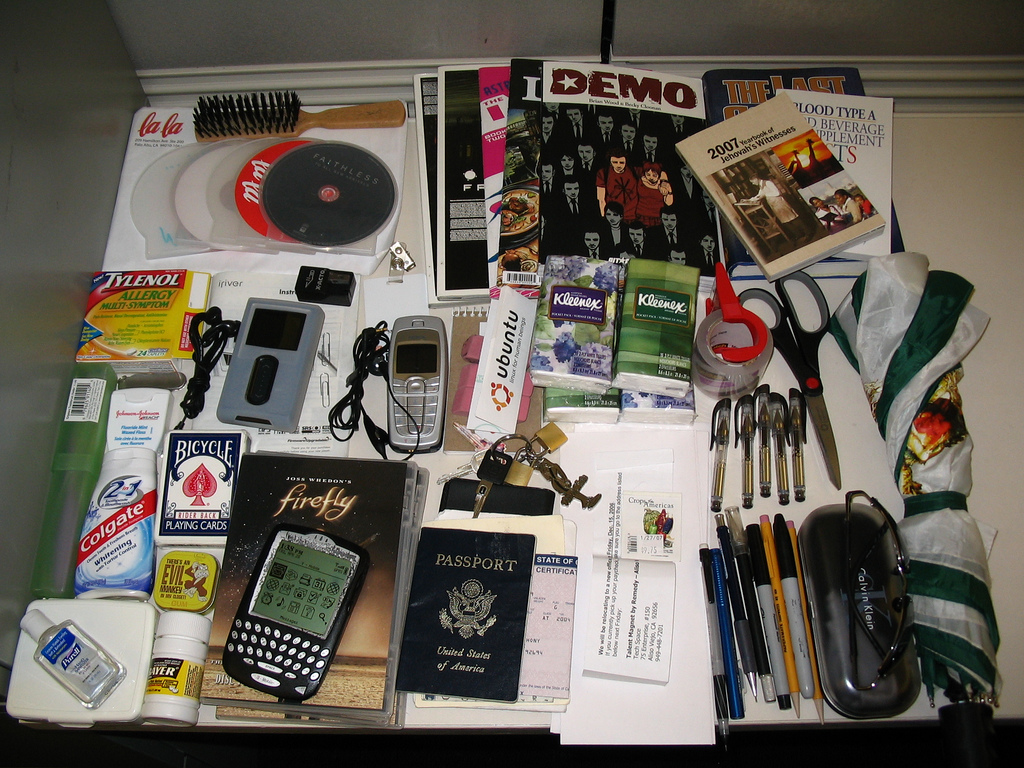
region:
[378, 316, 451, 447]
cell phone on the table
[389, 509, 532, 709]
passport on the table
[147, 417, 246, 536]
deck of card on the table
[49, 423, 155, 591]
toothpaste on the table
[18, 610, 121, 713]
hand sanitize on the table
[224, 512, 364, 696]
blackberry on the table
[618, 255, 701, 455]
kleenex on the table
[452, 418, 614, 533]
keyholder on the table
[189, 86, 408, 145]
a hairbrush with black bristles.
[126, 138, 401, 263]
compact discs in clear cases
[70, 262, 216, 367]
a box of Tylenol allergy medicine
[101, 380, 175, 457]
small container of dental floss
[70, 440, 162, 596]
container of toothpaste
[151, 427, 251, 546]
a box of bicycle brand playing cards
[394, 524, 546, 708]
a black passport with silver writting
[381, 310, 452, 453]
a silver cellphone.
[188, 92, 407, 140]
the brush is brown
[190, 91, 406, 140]
the black bristles on the brown brush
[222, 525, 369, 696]
the electronic device is black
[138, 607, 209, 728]
the white bottle of medicine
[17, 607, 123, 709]
the small clear bottle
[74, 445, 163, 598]
the bottle of toothpaste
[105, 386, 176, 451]
the container of floss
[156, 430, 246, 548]
the deck of cards in the blue,white and red box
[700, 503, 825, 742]
the pencils and pens grouped together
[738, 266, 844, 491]
the scissors has a black handle and a long blade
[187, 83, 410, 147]
Brown hairbrush with black thistles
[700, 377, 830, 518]
Five black ink pens with caps on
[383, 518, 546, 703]
Passport book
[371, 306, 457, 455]
Silver Nokia phone turned off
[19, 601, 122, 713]
Bottle of hand soap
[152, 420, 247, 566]
Blue pack of bicycle playing cards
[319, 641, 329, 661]
silver button on device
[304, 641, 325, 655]
silver button on device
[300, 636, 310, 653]
silver button on device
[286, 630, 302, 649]
silver button on device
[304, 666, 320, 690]
silver button on device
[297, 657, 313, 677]
silver button on device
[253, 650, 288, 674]
silver button on device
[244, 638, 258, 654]
silver button on device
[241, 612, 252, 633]
silver button on device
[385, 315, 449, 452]
cell phone on cluttered desk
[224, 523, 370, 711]
blackberry style cell phone on cluttered desk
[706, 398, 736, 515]
ink pen on cluttered desk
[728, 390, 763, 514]
ink pen on cluttered desk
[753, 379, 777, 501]
ink pen on cluttered desk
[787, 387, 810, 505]
ink pen on cluttered desk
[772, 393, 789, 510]
ink pen on cluttered desk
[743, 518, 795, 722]
sharpie marker on cluttered desk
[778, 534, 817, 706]
sharpie marker on cluttered desk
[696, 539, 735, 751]
ink pen on cluttered desk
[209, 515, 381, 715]
Cell phone on the table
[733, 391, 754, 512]
pen on the table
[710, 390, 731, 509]
pen on the table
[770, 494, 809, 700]
pen on the table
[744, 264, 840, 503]
scissors on the table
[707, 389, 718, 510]
An item used to write.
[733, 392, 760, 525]
An item used to write.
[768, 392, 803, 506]
An item used to write.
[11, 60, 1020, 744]
collection of items on a counter